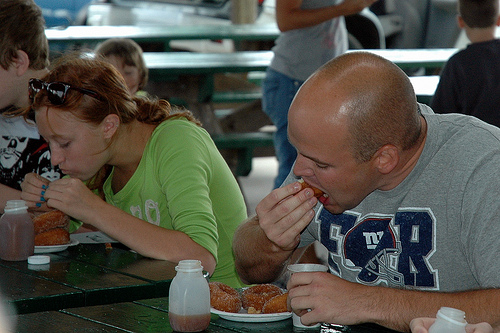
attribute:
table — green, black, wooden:
[88, 259, 122, 283]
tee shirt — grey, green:
[441, 150, 476, 217]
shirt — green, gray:
[163, 141, 210, 211]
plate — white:
[226, 310, 271, 323]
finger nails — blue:
[35, 183, 49, 208]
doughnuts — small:
[34, 211, 72, 242]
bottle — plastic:
[9, 223, 29, 260]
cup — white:
[287, 262, 330, 278]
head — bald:
[282, 57, 427, 186]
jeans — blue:
[261, 69, 286, 171]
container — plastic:
[419, 301, 477, 332]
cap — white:
[22, 252, 57, 270]